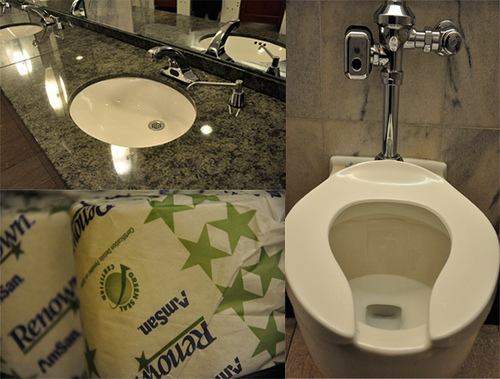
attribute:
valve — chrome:
[333, 3, 466, 168]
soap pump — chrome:
[255, 40, 282, 78]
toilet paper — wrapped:
[53, 179, 296, 370]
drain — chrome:
[144, 113, 165, 133]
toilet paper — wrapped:
[68, 199, 294, 351]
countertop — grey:
[0, 2, 285, 189]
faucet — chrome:
[145, 43, 199, 84]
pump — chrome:
[163, 67, 293, 159]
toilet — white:
[286, 151, 497, 376]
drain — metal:
[146, 119, 166, 131]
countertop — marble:
[174, 82, 286, 155]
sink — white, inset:
[0, 14, 47, 48]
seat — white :
[283, 160, 498, 346]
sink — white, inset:
[49, 68, 216, 160]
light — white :
[199, 122, 211, 132]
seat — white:
[289, 153, 487, 374]